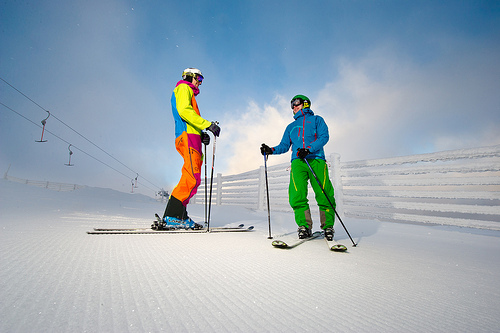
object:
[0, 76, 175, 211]
ski lift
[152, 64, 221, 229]
person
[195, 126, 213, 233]
ski pole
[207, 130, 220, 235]
ski pole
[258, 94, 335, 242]
person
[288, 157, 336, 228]
pants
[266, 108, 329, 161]
jacket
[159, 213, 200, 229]
ski boot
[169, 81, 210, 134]
jacket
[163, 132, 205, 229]
pants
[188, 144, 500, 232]
fence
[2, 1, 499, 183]
sky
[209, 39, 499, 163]
cloud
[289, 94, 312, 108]
helmet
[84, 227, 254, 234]
ski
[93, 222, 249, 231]
ski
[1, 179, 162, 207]
hill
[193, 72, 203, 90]
face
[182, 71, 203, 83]
goggles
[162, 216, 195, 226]
foot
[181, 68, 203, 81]
helmet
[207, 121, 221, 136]
glove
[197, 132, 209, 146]
glove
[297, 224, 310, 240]
binding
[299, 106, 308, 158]
zipper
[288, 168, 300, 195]
zipper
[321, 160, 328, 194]
zipper